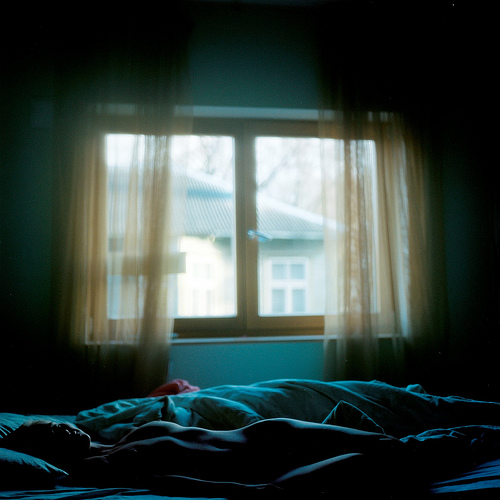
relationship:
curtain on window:
[49, 0, 194, 394] [65, 87, 440, 357]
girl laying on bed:
[6, 417, 481, 491] [0, 376, 498, 496]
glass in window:
[254, 137, 329, 315] [244, 123, 381, 331]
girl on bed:
[6, 417, 481, 491] [0, 415, 498, 499]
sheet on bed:
[19, 487, 136, 499] [0, 376, 498, 496]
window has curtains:
[70, 109, 430, 352] [315, 115, 437, 342]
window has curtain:
[100, 116, 410, 334] [49, 0, 194, 394]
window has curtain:
[100, 116, 410, 334] [319, 0, 449, 383]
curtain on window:
[49, 0, 194, 394] [76, 90, 421, 342]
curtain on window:
[319, 0, 449, 383] [76, 90, 421, 342]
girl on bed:
[6, 417, 481, 491] [0, 376, 498, 496]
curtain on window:
[53, 79, 193, 394] [105, 132, 235, 317]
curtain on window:
[318, 90, 445, 380] [255, 136, 377, 316]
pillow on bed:
[1, 414, 69, 486] [0, 376, 498, 496]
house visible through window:
[99, 163, 384, 332] [65, 87, 440, 357]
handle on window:
[247, 230, 272, 243] [100, 116, 410, 334]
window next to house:
[259, 253, 319, 321] [105, 158, 374, 328]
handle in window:
[247, 230, 271, 240] [65, 87, 440, 357]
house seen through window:
[105, 163, 345, 319] [100, 116, 410, 334]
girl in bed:
[6, 417, 481, 491] [0, 376, 498, 496]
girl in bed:
[6, 413, 497, 492] [304, 427, 435, 472]